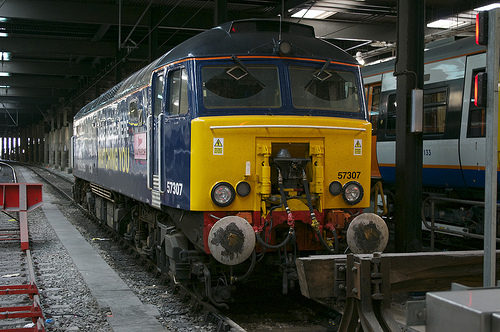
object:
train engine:
[65, 21, 371, 301]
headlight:
[210, 181, 237, 207]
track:
[0, 157, 79, 332]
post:
[390, 0, 425, 252]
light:
[286, 2, 339, 23]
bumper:
[192, 160, 393, 308]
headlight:
[344, 182, 361, 203]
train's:
[67, 15, 394, 312]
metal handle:
[155, 113, 166, 191]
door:
[145, 64, 173, 208]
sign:
[131, 130, 149, 160]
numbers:
[165, 181, 184, 196]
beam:
[393, 1, 424, 253]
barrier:
[296, 250, 499, 331]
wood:
[296, 252, 499, 305]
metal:
[333, 255, 401, 332]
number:
[335, 170, 361, 180]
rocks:
[24, 215, 121, 332]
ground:
[2, 164, 227, 332]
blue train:
[66, 16, 388, 313]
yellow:
[189, 114, 373, 209]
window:
[160, 66, 192, 120]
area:
[281, 0, 500, 138]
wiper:
[231, 54, 280, 108]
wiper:
[293, 54, 335, 109]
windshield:
[160, 57, 372, 116]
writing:
[95, 143, 130, 173]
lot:
[0, 2, 499, 332]